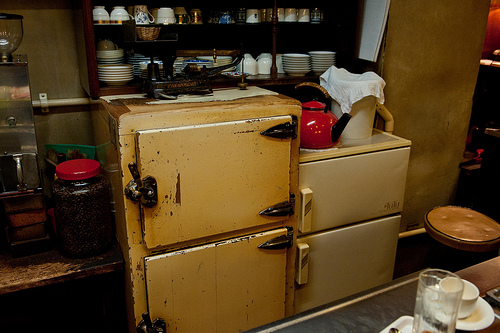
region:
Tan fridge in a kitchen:
[120, 117, 311, 270]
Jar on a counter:
[48, 154, 141, 266]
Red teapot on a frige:
[277, 83, 366, 160]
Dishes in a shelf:
[99, 45, 334, 84]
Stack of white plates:
[96, 59, 135, 100]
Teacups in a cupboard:
[93, 4, 200, 24]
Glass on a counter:
[406, 271, 462, 332]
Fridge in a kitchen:
[296, 144, 439, 313]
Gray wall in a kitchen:
[383, 41, 497, 152]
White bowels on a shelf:
[283, 43, 347, 75]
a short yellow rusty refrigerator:
[118, 108, 299, 329]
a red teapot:
[301, 92, 353, 146]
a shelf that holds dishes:
[95, 1, 367, 85]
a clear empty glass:
[415, 264, 465, 331]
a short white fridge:
[287, 140, 421, 311]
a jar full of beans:
[50, 160, 121, 251]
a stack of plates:
[95, 61, 135, 85]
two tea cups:
[91, 2, 135, 24]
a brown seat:
[430, 198, 498, 248]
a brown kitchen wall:
[402, 12, 470, 120]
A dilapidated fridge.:
[115, 98, 303, 329]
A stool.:
[422, 195, 497, 255]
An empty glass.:
[407, 252, 457, 327]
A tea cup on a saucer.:
[415, 270, 490, 330]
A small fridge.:
[285, 127, 410, 327]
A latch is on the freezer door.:
[111, 100, 291, 255]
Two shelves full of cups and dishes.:
[70, 0, 370, 90]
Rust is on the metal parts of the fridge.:
[105, 97, 300, 327]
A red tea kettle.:
[291, 80, 351, 160]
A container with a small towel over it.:
[325, 65, 385, 142]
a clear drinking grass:
[408, 266, 467, 331]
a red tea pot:
[288, 79, 353, 149]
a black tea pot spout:
[329, 108, 354, 147]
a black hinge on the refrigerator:
[256, 116, 299, 145]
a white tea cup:
[425, 274, 487, 321]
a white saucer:
[419, 279, 498, 330]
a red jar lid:
[51, 153, 104, 188]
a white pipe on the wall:
[27, 90, 99, 116]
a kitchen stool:
[422, 199, 498, 252]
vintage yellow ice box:
[94, 76, 306, 331]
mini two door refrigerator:
[280, 128, 407, 283]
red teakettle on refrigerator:
[281, 79, 366, 153]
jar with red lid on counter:
[39, 153, 126, 267]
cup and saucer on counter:
[410, 262, 499, 332]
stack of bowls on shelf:
[277, 39, 343, 84]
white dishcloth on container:
[311, 50, 391, 118]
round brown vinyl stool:
[420, 191, 497, 265]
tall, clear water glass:
[396, 256, 459, 331]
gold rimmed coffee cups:
[92, 5, 187, 29]